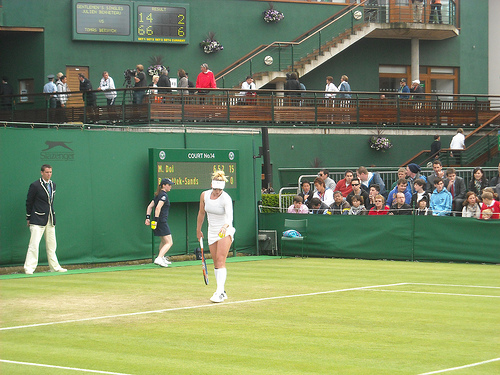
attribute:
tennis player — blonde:
[196, 170, 236, 302]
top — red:
[192, 64, 218, 89]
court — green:
[35, 254, 497, 371]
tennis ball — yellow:
[214, 230, 226, 243]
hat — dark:
[141, 183, 199, 204]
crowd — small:
[277, 167, 499, 224]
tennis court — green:
[1, 253, 497, 368]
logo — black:
[39, 136, 80, 169]